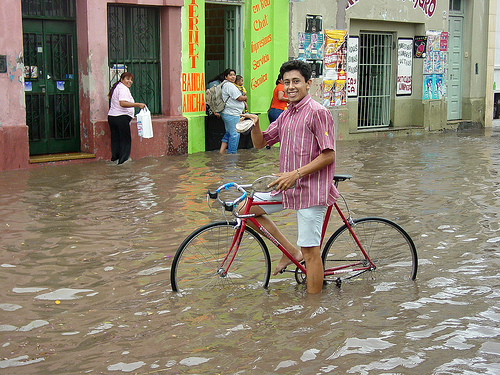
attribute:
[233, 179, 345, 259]
short — white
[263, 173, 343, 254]
short — white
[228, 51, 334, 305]
man — finger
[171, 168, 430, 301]
bicycle — black, red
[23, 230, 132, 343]
street — flooded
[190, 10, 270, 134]
wall — orange, green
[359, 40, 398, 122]
front — Gated iron door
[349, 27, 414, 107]
wall — Posters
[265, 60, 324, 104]
man — head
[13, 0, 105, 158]
door — green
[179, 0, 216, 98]
writing — orange